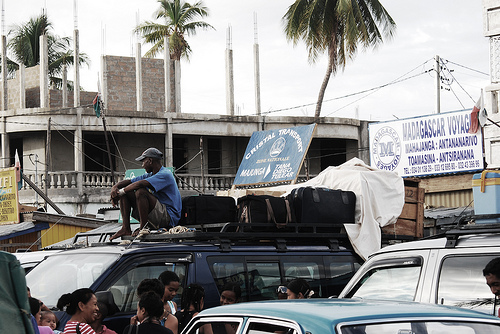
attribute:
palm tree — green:
[286, 2, 394, 120]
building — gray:
[2, 36, 370, 189]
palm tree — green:
[134, 1, 211, 115]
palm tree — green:
[1, 10, 86, 103]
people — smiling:
[60, 286, 98, 333]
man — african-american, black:
[112, 148, 182, 242]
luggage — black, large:
[167, 188, 358, 238]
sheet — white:
[220, 157, 403, 266]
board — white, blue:
[367, 110, 486, 182]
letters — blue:
[397, 116, 480, 174]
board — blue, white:
[230, 124, 318, 189]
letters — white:
[237, 130, 303, 179]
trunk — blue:
[471, 167, 499, 218]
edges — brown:
[472, 169, 500, 190]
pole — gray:
[254, 47, 262, 114]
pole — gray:
[226, 49, 236, 119]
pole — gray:
[165, 33, 173, 112]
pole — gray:
[134, 39, 145, 115]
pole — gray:
[73, 29, 83, 110]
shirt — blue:
[132, 163, 183, 231]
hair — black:
[55, 286, 96, 317]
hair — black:
[140, 291, 163, 315]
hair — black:
[286, 277, 313, 299]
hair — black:
[183, 282, 204, 323]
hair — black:
[158, 271, 179, 286]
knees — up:
[118, 179, 154, 208]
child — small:
[40, 311, 59, 333]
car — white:
[340, 228, 499, 312]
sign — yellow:
[0, 165, 22, 226]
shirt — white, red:
[65, 319, 95, 333]